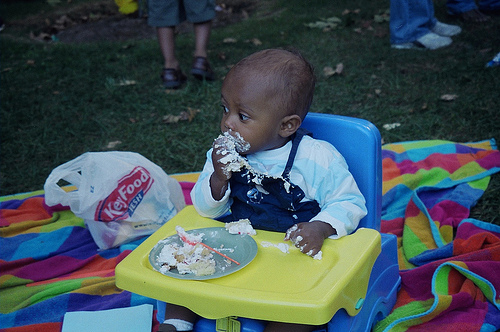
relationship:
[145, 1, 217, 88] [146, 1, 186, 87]
person has leg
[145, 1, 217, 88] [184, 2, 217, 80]
person has leg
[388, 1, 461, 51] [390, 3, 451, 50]
person has leg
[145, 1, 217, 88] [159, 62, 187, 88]
person has foot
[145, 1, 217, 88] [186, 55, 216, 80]
person has foot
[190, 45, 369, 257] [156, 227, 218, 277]
baby eating food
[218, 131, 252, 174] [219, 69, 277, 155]
food on face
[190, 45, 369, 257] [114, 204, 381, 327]
baby has tray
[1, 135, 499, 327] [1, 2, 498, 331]
beach blanket on ground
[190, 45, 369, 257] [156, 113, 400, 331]
baby sitting in chair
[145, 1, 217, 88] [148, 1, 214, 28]
person wearing shorts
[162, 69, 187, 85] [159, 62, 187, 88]
shoe on foot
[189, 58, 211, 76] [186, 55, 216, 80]
shoe on foot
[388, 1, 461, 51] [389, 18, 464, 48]
person wearing tennis shoes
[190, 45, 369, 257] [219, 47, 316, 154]
baby has head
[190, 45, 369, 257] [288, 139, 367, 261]
baby has arm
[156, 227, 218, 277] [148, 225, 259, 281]
food on plate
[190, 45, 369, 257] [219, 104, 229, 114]
baby has right eye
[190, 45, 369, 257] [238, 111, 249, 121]
baby has left eye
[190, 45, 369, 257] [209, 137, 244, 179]
baby has right hand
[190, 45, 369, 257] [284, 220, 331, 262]
baby has left hand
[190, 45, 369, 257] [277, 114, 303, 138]
baby has left ear